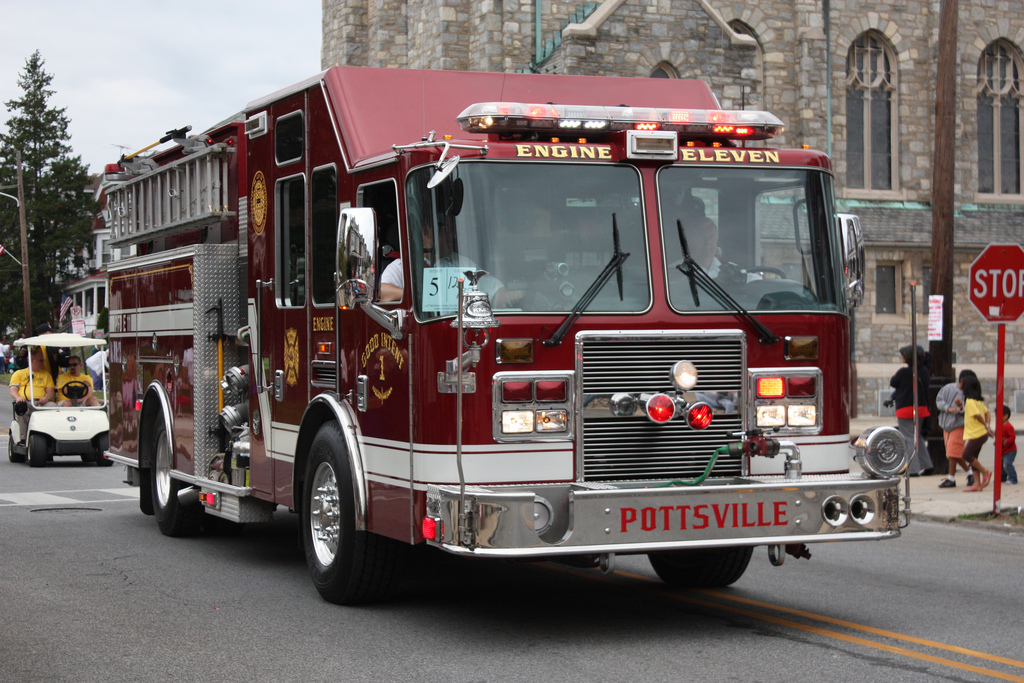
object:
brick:
[909, 141, 925, 153]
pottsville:
[621, 501, 790, 533]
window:
[403, 159, 653, 324]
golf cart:
[8, 332, 115, 468]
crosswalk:
[0, 487, 142, 509]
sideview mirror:
[334, 207, 406, 339]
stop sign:
[966, 242, 1024, 516]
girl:
[958, 376, 994, 492]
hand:
[988, 430, 994, 439]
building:
[321, 0, 1022, 416]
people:
[884, 344, 994, 492]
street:
[0, 380, 1024, 683]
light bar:
[457, 102, 785, 141]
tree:
[0, 49, 99, 343]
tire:
[299, 419, 397, 606]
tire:
[27, 434, 46, 468]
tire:
[8, 432, 25, 464]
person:
[890, 344, 936, 477]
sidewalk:
[848, 414, 1024, 525]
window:
[274, 172, 309, 309]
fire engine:
[102, 66, 912, 607]